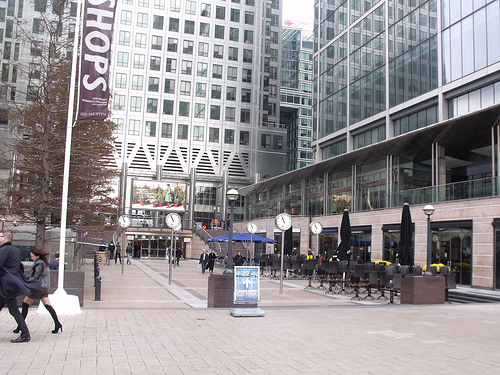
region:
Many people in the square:
[5, 218, 395, 351]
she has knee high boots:
[5, 304, 65, 332]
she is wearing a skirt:
[25, 278, 50, 304]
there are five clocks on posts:
[100, 207, 342, 246]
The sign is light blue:
[234, 263, 269, 311]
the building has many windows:
[2, 8, 276, 183]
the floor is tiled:
[88, 313, 419, 370]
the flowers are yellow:
[417, 260, 454, 273]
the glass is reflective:
[298, 12, 498, 114]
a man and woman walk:
[4, 223, 82, 337]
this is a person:
[4, 238, 66, 346]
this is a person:
[1, 230, 38, 351]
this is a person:
[223, 240, 259, 299]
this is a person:
[197, 245, 223, 282]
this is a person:
[189, 246, 211, 284]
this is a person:
[286, 243, 306, 276]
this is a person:
[230, 235, 250, 281]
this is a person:
[269, 223, 303, 285]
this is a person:
[315, 243, 359, 282]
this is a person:
[117, 233, 144, 267]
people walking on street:
[1, 222, 68, 350]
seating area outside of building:
[261, 248, 424, 300]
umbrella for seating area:
[396, 198, 414, 270]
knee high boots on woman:
[18, 303, 67, 336]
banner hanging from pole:
[63, 3, 127, 130]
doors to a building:
[138, 241, 163, 258]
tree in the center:
[8, 8, 119, 249]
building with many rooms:
[5, 0, 298, 152]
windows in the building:
[146, 56, 207, 76]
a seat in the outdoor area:
[350, 262, 367, 284]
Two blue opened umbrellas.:
[205, 231, 281, 244]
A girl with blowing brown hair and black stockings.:
[13, 245, 65, 334]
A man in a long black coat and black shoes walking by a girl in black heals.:
[0, 228, 30, 341]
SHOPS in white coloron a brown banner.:
[82, 0, 117, 92]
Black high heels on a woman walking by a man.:
[11, 322, 65, 336]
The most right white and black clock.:
[308, 220, 324, 235]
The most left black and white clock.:
[116, 215, 133, 228]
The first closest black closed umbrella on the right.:
[398, 200, 414, 265]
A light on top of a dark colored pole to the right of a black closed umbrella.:
[422, 203, 434, 272]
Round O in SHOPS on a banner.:
[86, 28, 111, 55]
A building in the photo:
[135, 52, 227, 135]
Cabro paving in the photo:
[144, 313, 219, 350]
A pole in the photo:
[219, 209, 243, 255]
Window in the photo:
[165, 87, 177, 115]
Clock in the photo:
[270, 207, 300, 237]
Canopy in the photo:
[284, 142, 376, 180]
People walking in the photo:
[2, 242, 51, 339]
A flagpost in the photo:
[60, 124, 74, 257]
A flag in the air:
[76, 30, 109, 118]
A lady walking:
[25, 248, 69, 328]